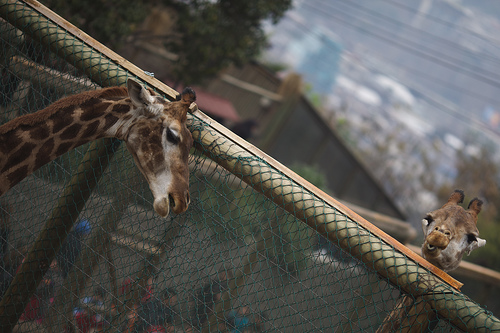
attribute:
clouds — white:
[363, 56, 455, 148]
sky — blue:
[248, 0, 498, 199]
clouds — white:
[324, 28, 499, 213]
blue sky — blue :
[259, 0, 497, 232]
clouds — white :
[366, 65, 443, 148]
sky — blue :
[268, 2, 498, 241]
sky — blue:
[261, 8, 494, 250]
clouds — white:
[394, 52, 487, 112]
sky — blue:
[389, 3, 499, 62]